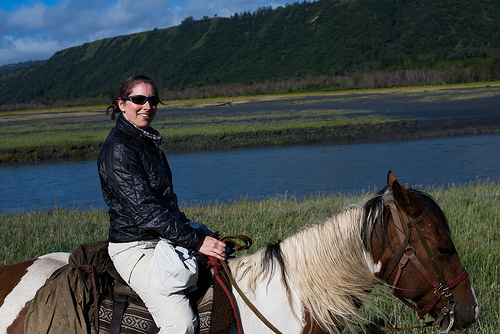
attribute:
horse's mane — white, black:
[254, 198, 382, 329]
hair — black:
[409, 187, 446, 225]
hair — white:
[322, 247, 350, 278]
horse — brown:
[0, 167, 479, 332]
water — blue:
[274, 164, 309, 191]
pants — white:
[108, 239, 200, 331]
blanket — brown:
[20, 246, 150, 331]